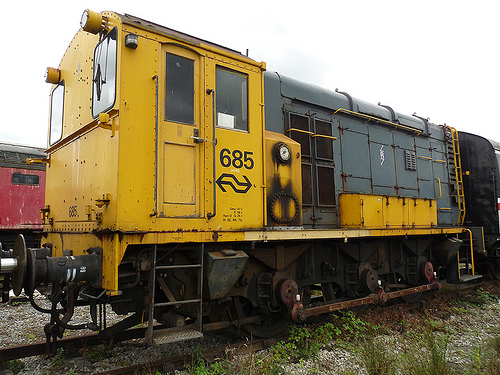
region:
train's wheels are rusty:
[249, 264, 476, 329]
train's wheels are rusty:
[282, 273, 454, 331]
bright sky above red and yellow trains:
[5, 3, 495, 174]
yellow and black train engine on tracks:
[11, 7, 486, 368]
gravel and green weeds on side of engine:
[5, 252, 493, 365]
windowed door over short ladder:
[149, 35, 211, 355]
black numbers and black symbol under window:
[206, 52, 263, 227]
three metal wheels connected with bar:
[268, 252, 444, 326]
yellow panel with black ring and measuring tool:
[262, 127, 302, 229]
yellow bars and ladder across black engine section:
[287, 100, 468, 227]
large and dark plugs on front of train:
[3, 226, 119, 345]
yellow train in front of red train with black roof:
[3, 15, 125, 235]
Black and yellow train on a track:
[41, 5, 498, 342]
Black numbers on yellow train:
[214, 147, 254, 193]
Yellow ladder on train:
[437, 122, 464, 227]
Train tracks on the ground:
[1, 300, 301, 370]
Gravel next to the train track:
[0, 300, 130, 371]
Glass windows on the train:
[45, 22, 250, 147]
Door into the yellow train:
[155, 37, 206, 222]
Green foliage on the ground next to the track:
[166, 281, 498, 373]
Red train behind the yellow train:
[1, 143, 50, 243]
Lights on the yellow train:
[43, 8, 110, 85]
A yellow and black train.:
[81, 43, 468, 291]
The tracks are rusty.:
[58, 318, 131, 372]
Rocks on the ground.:
[294, 335, 495, 370]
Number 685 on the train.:
[214, 136, 249, 181]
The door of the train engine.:
[163, 48, 210, 213]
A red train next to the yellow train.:
[4, 138, 56, 243]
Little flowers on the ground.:
[278, 313, 379, 353]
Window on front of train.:
[83, 44, 125, 126]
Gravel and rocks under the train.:
[85, 336, 209, 368]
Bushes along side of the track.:
[276, 321, 378, 342]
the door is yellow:
[143, 25, 225, 243]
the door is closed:
[143, 30, 213, 230]